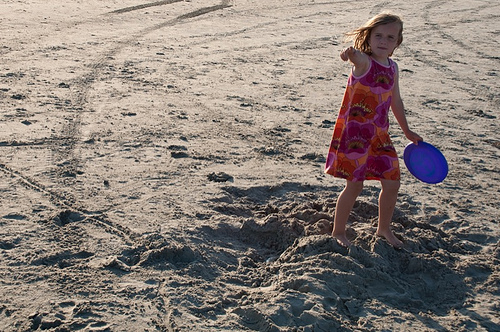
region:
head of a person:
[355, 5, 407, 58]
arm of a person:
[323, 42, 373, 72]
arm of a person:
[385, 93, 417, 144]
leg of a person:
[322, 170, 362, 247]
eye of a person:
[365, 25, 389, 40]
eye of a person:
[378, 31, 398, 46]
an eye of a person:
[371, 28, 385, 38]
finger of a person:
[338, 45, 351, 62]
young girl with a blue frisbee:
[295, 5, 473, 270]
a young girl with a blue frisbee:
[290, 5, 475, 277]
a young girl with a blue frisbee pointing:
[282, 6, 475, 281]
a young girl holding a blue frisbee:
[300, 7, 470, 258]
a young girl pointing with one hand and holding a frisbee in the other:
[292, 4, 480, 308]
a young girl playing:
[296, 5, 468, 280]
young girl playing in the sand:
[287, 5, 499, 254]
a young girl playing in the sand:
[290, 5, 474, 320]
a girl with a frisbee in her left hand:
[304, 7, 476, 269]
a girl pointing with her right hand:
[313, 6, 469, 286]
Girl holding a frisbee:
[402, 137, 452, 187]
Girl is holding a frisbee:
[401, 133, 451, 190]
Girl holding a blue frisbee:
[398, 135, 454, 189]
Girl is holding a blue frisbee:
[400, 135, 449, 188]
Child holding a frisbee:
[401, 139, 451, 186]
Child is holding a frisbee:
[397, 135, 454, 186]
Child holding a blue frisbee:
[398, 135, 457, 192]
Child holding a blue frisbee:
[393, 137, 455, 192]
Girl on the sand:
[323, 6, 458, 253]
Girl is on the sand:
[327, 9, 459, 251]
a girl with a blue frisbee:
[402, 133, 452, 186]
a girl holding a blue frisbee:
[312, 12, 449, 254]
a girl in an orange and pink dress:
[320, 45, 399, 186]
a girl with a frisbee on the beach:
[322, 10, 451, 251]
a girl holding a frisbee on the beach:
[320, 12, 447, 254]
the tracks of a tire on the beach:
[7, 0, 243, 327]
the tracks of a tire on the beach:
[365, 0, 497, 100]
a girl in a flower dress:
[320, 47, 404, 181]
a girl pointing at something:
[318, 7, 449, 255]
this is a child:
[317, 12, 413, 243]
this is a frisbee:
[402, 139, 447, 187]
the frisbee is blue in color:
[402, 140, 449, 182]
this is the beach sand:
[198, 171, 310, 299]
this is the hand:
[332, 41, 367, 71]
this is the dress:
[324, 81, 385, 172]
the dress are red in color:
[334, 81, 380, 166]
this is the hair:
[350, 22, 371, 47]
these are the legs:
[329, 169, 403, 243]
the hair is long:
[354, 24, 371, 48]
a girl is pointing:
[337, 11, 447, 243]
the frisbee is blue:
[401, 139, 448, 182]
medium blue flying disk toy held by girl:
[402, 138, 448, 185]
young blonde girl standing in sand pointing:
[325, 10, 423, 247]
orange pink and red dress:
[325, 50, 401, 180]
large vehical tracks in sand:
[13, 0, 235, 329]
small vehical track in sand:
[1, 158, 144, 249]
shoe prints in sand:
[167, 140, 236, 189]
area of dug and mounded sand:
[132, 178, 482, 330]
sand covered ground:
[0, 0, 499, 330]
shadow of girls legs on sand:
[409, 303, 499, 329]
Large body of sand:
[18, 55, 186, 190]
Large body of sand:
[36, 204, 174, 312]